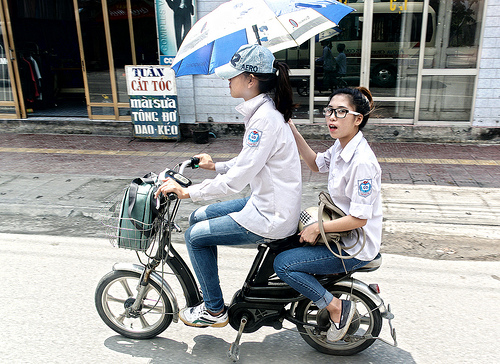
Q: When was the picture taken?
A: During the day.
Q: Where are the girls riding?
A: On the street.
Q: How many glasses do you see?
A: 1.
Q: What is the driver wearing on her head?
A: A hat.